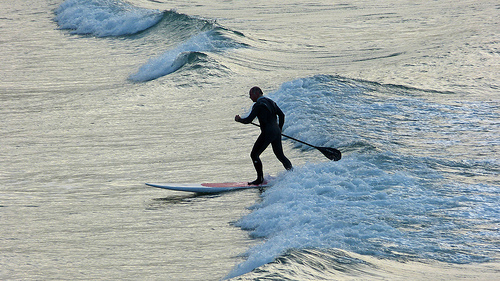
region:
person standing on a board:
[121, 78, 349, 210]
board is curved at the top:
[142, 175, 209, 202]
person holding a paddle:
[222, 68, 355, 190]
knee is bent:
[244, 144, 258, 164]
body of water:
[0, 0, 497, 279]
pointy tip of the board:
[138, 178, 153, 190]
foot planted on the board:
[243, 172, 270, 189]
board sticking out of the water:
[145, 172, 268, 200]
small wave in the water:
[45, 0, 247, 87]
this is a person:
[218, 71, 306, 186]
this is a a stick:
[243, 108, 345, 170]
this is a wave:
[243, 175, 327, 258]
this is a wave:
[123, 37, 223, 84]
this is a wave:
[63, 8, 164, 46]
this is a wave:
[266, 194, 316, 271]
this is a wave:
[331, 172, 373, 232]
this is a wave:
[295, 81, 330, 132]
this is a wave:
[283, 82, 317, 136]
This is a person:
[143, 79, 358, 212]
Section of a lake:
[366, 182, 496, 257]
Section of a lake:
[41, 175, 109, 267]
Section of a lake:
[270, 208, 399, 279]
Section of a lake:
[104, 35, 215, 117]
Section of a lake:
[308, 27, 473, 107]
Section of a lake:
[10, 125, 77, 279]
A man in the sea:
[235, 77, 322, 195]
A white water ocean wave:
[261, 57, 345, 134]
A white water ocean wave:
[135, 20, 240, 110]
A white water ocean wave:
[67, 0, 157, 27]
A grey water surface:
[30, 206, 147, 280]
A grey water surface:
[14, 94, 159, 164]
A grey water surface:
[7, 7, 149, 79]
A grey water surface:
[387, 170, 465, 277]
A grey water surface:
[402, 47, 493, 117]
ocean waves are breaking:
[72, 9, 213, 101]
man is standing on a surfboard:
[228, 80, 300, 180]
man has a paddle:
[238, 115, 344, 175]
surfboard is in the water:
[140, 172, 243, 199]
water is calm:
[38, 118, 110, 231]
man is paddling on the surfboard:
[96, 82, 366, 203]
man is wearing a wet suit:
[228, 107, 297, 189]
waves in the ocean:
[123, 22, 222, 86]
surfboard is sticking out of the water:
[145, 155, 192, 204]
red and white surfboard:
[143, 180, 243, 192]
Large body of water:
[23, 45, 140, 130]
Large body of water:
[11, 75, 123, 148]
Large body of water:
[353, 13, 463, 101]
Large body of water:
[351, 196, 470, 253]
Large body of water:
[321, 38, 439, 122]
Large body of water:
[317, 174, 428, 236]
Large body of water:
[379, 148, 499, 233]